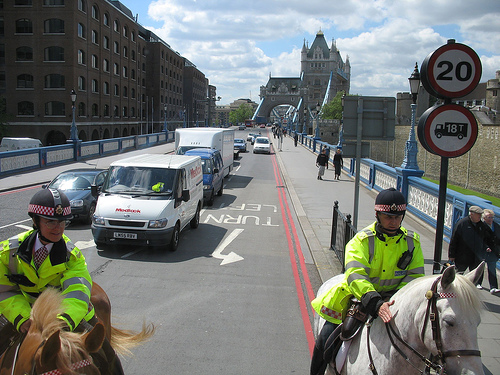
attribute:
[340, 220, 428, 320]
safety jacket — yellow 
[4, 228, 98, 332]
safety jacket — yellow 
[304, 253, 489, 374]
horse — brown , white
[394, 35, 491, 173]
sign — traffic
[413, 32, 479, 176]
sign — traffic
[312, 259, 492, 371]
horse — white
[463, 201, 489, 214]
hat — brown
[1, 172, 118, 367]
horse — brown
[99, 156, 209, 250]
van — white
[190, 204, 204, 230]
tire — back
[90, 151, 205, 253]
van — white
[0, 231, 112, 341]
coat — fluorescent green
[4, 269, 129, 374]
horse — brown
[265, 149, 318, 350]
lines — red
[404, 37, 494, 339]
street sign — british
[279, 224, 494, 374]
horse — white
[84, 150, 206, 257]
van — white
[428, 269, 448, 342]
horse — white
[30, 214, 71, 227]
glasses — clear